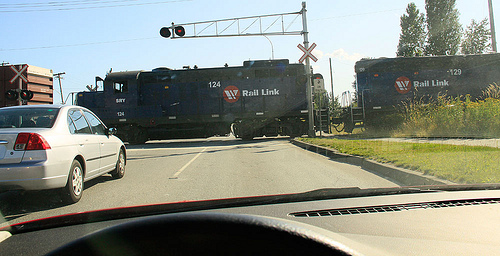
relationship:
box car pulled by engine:
[0, 61, 55, 106] [74, 58, 331, 143]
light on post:
[174, 25, 185, 36] [299, 0, 317, 138]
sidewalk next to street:
[317, 133, 499, 150] [1, 142, 414, 228]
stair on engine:
[312, 109, 332, 132] [74, 58, 331, 143]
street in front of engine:
[1, 142, 414, 228] [74, 58, 331, 143]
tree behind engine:
[395, 1, 428, 56] [74, 58, 331, 143]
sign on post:
[296, 41, 320, 68] [299, 0, 317, 138]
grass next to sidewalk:
[300, 135, 499, 193] [317, 133, 499, 150]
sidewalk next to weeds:
[317, 133, 499, 150] [397, 84, 499, 137]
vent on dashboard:
[289, 195, 499, 220] [0, 188, 498, 255]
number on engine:
[207, 79, 222, 88] [74, 58, 331, 143]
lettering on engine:
[243, 87, 281, 98] [74, 58, 331, 143]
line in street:
[170, 142, 212, 183] [1, 142, 414, 228]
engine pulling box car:
[74, 58, 331, 143] [0, 61, 55, 106]